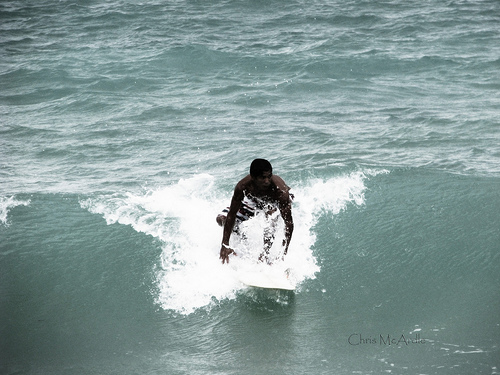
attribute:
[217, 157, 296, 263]
man — surfing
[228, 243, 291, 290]
surfboard — white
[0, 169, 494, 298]
wave — white, gray, small, gra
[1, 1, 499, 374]
ocean — blue, white, green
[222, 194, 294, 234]
trunks — striped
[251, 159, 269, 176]
hair — dark